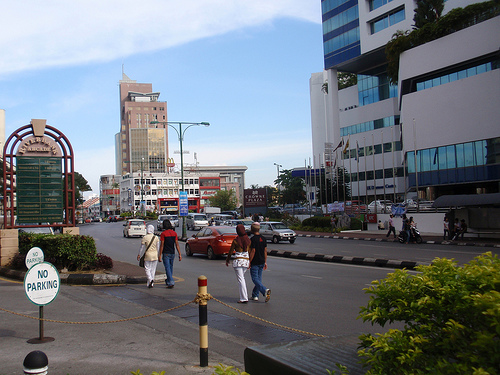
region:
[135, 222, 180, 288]
These are 2 people walking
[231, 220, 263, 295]
These are 2 people walking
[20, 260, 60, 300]
This is a no parking sign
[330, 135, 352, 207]
This is a flag pole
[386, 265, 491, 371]
This is a green bush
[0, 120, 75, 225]
This is a sign showing businesses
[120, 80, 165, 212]
This is a tall building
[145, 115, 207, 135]
These are street lights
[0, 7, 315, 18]
This is a cloud in the sky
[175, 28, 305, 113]
Blue sky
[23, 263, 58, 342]
a no parking sign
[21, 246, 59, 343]
two no parking signs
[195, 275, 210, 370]
a black and yellow striped pole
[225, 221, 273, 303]
a couple walking down the street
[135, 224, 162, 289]
a woman carrying a purse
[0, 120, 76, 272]
a large stone sign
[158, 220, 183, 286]
person in a red and black jacket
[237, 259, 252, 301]
a woman's white pants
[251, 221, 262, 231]
a man's stocking cap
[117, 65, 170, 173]
a tall building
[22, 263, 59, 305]
White no parking sign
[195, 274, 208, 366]
Black and orange chain pole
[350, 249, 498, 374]
Green and brown bush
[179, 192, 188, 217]
Blue and white street sign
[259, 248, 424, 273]
black and gray street divider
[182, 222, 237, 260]
Small luxury red car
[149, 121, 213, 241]
Large unlit street lights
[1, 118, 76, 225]
A riverbank sign of signs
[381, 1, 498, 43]
Brown window lined planter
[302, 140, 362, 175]
Small group of various flags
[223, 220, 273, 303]
couple walking down the street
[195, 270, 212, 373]
tan black and red pole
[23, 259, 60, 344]
small no parking sign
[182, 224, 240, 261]
red car in the street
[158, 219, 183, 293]
person in a black and red top walking down the street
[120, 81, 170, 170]
a couple of very tall buildings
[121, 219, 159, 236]
white vehicle on the street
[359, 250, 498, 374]
a bunch of bush leaves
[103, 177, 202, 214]
a large wide white building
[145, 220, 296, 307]
four people walking on street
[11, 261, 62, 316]
round white no parking sign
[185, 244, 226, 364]
yellow and black metal pole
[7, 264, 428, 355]
yellow ropes closing off parking lot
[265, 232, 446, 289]
white and black divider in road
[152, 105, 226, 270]
large two sided street lamp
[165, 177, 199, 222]
several signs on street lamp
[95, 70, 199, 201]
tall brown building in photogrpah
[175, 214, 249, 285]
red vehicle on road in photo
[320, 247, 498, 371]
green bush in photograph